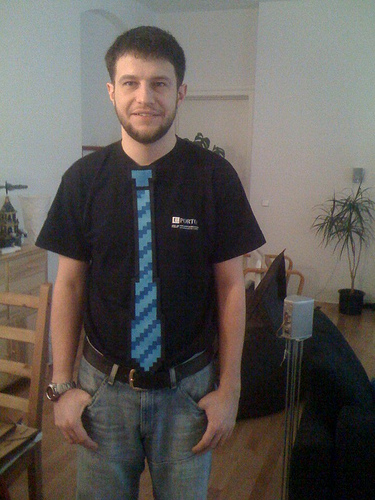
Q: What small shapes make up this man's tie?
A: Squares.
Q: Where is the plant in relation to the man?
A: Behind the man.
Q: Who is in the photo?
A: A man.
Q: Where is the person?
A: In a room.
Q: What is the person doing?
A: Standing.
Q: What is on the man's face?
A: A beard.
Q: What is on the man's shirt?
A: A tie.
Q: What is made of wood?
A: A shelf.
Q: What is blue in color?
A: Tie.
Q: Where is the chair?
A: Next to person.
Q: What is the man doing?
A: Smiling.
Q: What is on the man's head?
A: Hair.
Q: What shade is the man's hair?
A: Dark.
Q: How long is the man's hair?
A: Short.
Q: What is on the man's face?
A: A beard.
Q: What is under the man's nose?
A: A moustache.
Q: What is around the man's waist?
A: A belt.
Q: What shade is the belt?
A: Black.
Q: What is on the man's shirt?
A: Tie.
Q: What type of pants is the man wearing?
A: Blue jeans.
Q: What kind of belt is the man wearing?
A: Leather.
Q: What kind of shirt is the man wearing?
A: T shirt.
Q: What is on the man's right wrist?
A: Watch.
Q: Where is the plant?
A: Against the back wall.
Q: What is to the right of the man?
A: Chair.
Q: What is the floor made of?
A: Wood.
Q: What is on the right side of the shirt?
A: Logo.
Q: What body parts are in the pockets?
A: Thumbs.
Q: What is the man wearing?
A: A blue tie.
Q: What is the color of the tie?
A: Blue.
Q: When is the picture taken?
A: Daytime.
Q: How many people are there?
A: 1.